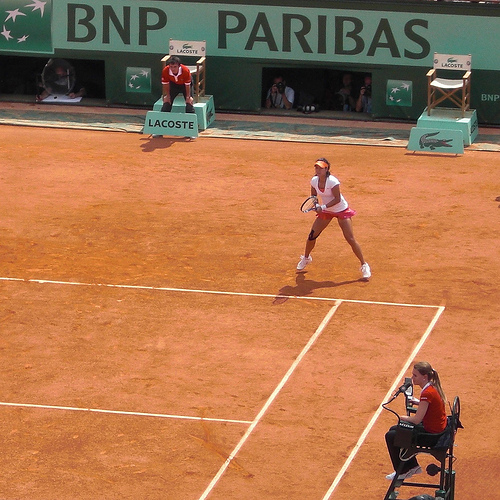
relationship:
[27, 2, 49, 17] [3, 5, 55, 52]
star on logo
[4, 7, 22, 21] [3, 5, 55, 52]
star on logo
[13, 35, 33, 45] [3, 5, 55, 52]
star on logo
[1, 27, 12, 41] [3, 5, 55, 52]
star on logo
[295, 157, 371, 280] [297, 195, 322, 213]
tennis player holding racket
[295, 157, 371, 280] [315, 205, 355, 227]
tennis player has shorts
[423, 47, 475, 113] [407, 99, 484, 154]
chair on block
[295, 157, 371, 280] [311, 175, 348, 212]
tennis player wearing shirt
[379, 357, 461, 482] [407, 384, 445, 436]
woman wearing shirt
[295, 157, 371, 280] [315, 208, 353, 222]
tennis player wearing a skirt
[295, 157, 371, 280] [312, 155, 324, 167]
tennis player wearing a visor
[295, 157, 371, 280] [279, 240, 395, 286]
tennis player wearing shoes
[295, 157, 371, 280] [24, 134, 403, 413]
tennis player playing tennis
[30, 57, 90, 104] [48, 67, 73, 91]
man holding tv camera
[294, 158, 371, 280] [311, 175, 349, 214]
tennis player in shirt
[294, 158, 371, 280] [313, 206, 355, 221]
tennis player in pink skirt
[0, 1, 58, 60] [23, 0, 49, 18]
logo of star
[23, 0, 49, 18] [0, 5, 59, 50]
star in a circle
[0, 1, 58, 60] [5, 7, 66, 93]
logo in corner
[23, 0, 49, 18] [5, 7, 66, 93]
star in corner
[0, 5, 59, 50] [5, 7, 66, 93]
circle in corner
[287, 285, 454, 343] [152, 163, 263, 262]
lines on ground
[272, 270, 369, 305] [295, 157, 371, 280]
shadow of tennis player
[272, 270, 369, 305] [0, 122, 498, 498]
shadow on ground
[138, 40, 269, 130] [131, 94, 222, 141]
guy standing above chair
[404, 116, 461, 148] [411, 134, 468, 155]
image of gator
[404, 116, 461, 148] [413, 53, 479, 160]
image on chair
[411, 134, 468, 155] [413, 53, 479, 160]
gator on chair